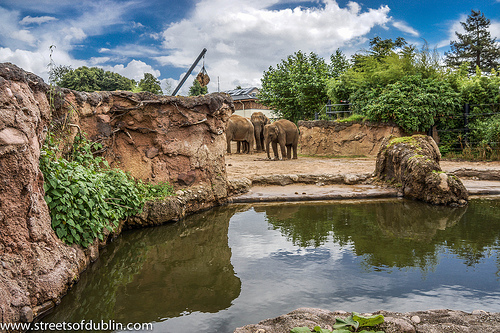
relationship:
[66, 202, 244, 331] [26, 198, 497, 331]
reflection on water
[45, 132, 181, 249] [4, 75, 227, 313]
vine on cliff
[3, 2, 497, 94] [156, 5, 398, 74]
sky with cloud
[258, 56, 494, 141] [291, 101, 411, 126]
foliage behind fence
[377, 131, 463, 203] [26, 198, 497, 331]
rock near water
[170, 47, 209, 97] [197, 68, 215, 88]
pole with bag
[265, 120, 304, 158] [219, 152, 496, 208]
elephant on dirt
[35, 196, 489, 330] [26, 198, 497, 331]
pool of water